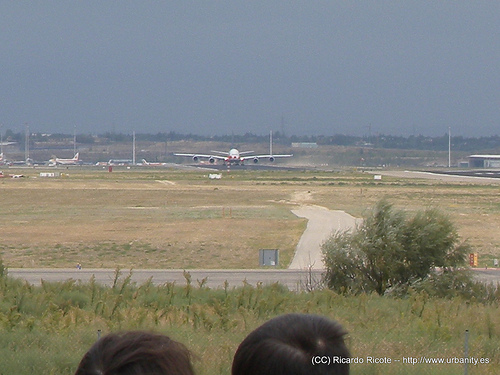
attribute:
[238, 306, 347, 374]
hair — service, thick, black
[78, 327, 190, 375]
person — electrical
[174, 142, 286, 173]
plane — landing, white, commercial, long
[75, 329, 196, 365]
hair — brown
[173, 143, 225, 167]
wing — long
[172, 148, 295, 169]
plane — landing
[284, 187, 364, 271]
road — small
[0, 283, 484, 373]
grass — tall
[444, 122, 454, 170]
post — lamp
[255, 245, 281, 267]
box — grey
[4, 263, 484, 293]
road — small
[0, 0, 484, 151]
skyline — hazy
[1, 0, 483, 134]
sky — clear, blue, dark, gray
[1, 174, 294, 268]
airfield — brown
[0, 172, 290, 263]
ground — bare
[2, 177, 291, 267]
grass — dead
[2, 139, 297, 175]
planes — many